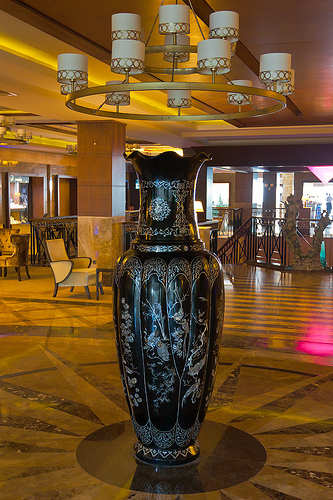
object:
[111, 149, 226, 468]
vase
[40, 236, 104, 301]
chair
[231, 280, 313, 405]
floor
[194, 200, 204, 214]
lamp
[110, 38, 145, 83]
light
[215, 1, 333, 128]
ceiling